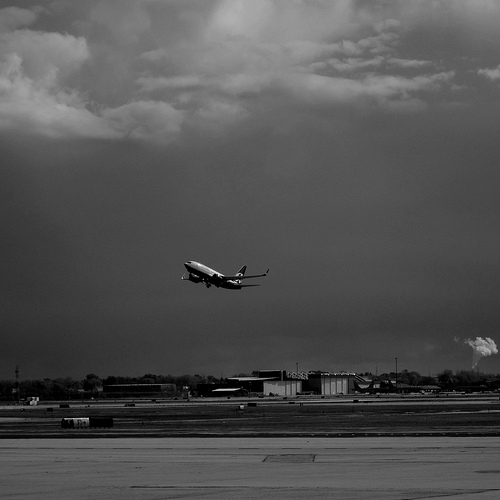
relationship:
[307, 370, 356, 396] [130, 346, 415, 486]
building adjacent to field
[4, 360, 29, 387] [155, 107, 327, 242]
tower in sky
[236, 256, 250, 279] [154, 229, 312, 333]
fin of airplane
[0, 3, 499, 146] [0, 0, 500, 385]
clouds in sky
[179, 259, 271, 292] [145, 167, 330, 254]
plane in air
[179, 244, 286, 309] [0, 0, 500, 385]
plane in sky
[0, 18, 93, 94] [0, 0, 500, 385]
cloud in sky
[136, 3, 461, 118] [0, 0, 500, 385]
cloud in sky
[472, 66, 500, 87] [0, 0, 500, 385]
clouds in sky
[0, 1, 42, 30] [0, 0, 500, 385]
cloud in sky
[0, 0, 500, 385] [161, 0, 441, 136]
sky with clouds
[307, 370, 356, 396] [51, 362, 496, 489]
building on ground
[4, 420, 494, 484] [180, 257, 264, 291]
runway for plane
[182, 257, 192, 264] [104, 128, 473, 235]
cockpit in sky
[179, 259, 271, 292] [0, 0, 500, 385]
plane in sky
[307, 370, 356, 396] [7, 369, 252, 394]
building front of trees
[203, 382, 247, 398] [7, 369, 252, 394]
building front of trees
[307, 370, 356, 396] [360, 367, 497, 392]
building front of trees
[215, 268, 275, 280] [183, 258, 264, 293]
wing of plane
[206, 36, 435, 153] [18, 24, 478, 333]
sky with clouds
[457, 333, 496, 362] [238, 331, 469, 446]
smoke near by building